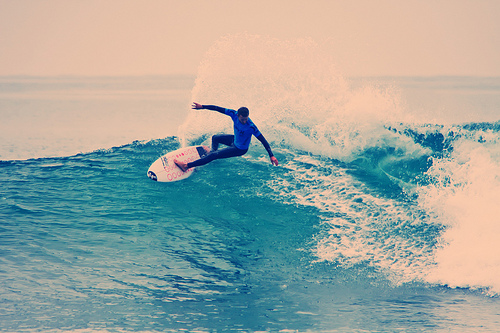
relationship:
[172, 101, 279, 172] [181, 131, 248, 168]
man has pants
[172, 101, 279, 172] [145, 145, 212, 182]
man on surfboard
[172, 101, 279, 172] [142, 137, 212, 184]
man riding surboard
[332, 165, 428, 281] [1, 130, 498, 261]
foam in front of a wave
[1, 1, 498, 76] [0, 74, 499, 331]
skies over ocean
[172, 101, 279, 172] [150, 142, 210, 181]
man on a surfboard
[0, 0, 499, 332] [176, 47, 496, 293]
blue waters behind splash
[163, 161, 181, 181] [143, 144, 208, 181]
red lettering on surfboard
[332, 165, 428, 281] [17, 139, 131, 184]
foam in front of wave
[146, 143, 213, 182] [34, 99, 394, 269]
board on ocean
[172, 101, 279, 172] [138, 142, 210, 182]
man on surfboard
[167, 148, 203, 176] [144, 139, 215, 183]
pink rings on surfboard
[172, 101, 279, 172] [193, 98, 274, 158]
man has shirt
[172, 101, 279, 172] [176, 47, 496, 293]
man riding splash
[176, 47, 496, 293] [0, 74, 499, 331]
splash in ocean